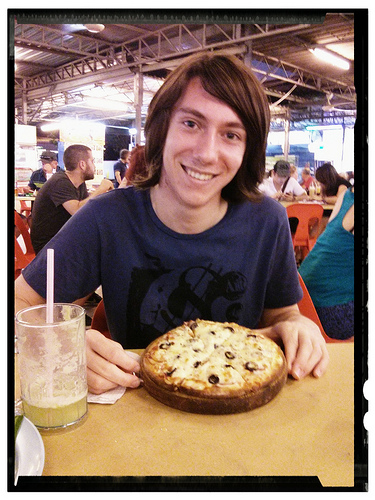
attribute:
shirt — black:
[27, 52, 323, 377]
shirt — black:
[213, 227, 237, 254]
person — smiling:
[58, 55, 301, 394]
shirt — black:
[54, 178, 321, 339]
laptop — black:
[15, 472, 336, 497]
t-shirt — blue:
[21, 183, 303, 351]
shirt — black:
[22, 182, 313, 348]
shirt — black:
[29, 183, 302, 358]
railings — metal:
[37, 30, 143, 89]